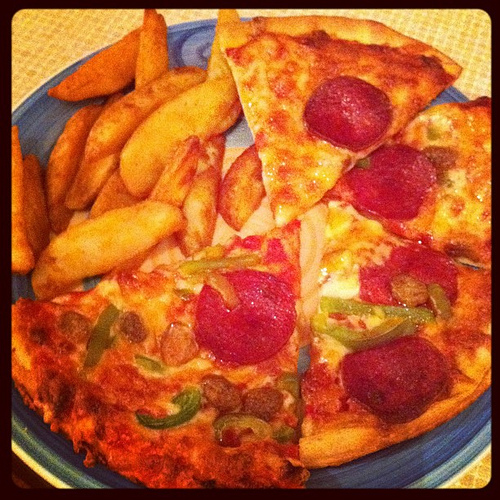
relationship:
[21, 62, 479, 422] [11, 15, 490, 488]
food on plate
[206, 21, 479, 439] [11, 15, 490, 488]
pizza on plate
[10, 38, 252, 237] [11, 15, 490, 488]
fries on plate